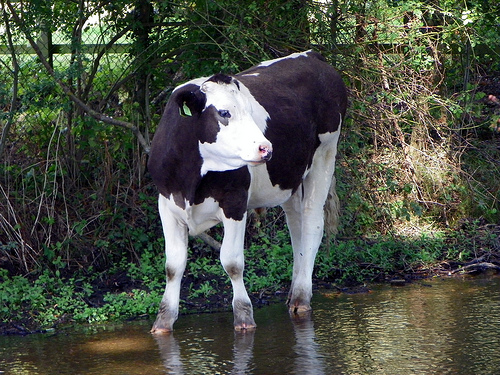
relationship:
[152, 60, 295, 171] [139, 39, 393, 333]
head of cow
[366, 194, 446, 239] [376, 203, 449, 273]
sun shining on grass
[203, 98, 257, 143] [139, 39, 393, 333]
eye of cow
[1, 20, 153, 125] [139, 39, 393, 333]
fence behind cow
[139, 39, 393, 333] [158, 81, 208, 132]
cow has ear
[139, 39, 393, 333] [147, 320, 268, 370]
cow has hooves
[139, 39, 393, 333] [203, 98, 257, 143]
cow has eye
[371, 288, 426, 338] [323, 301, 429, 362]
light on water